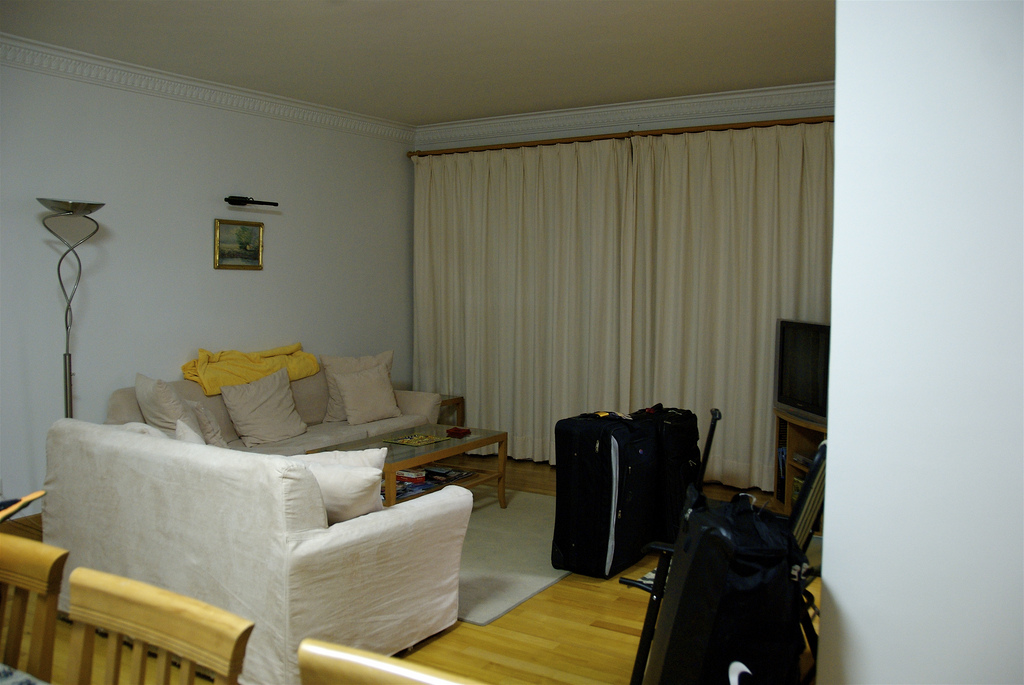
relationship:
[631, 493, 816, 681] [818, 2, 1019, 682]
luggage against wall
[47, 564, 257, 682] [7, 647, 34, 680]
chair near table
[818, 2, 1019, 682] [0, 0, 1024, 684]
wall on side building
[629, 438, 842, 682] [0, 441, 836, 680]
suitcases on ground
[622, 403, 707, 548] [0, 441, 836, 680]
suitcase on ground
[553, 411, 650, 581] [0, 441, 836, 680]
suitcase on ground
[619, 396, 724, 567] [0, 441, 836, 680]
suitcase on ground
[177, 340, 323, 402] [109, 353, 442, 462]
blanket on couch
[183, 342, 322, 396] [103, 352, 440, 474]
blanket on couch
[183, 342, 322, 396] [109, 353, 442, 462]
blanket on couch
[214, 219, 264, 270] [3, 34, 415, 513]
picture on wall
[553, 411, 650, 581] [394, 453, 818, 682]
suitcase on floor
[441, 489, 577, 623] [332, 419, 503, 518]
rug under table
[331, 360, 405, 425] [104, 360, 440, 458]
pillow on a couch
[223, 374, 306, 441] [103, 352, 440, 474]
pillow on a couch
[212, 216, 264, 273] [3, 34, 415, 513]
picture on a wall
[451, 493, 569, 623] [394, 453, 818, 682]
carpet on sa floor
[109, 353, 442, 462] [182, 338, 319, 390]
couch on blanket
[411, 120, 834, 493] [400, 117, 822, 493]
window on a window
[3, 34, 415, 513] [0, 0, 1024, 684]
wall on building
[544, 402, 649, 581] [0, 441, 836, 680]
suitcase on ground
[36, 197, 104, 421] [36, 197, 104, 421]
lamp on lamp